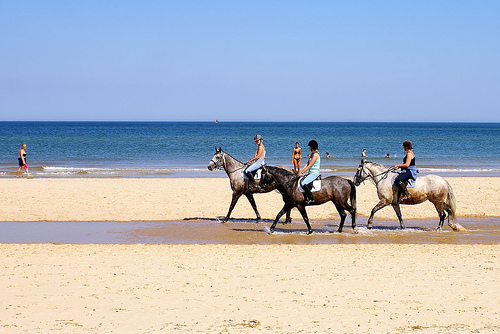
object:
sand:
[0, 242, 498, 334]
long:
[447, 180, 458, 219]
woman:
[393, 140, 416, 201]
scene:
[0, 119, 499, 334]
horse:
[353, 158, 462, 230]